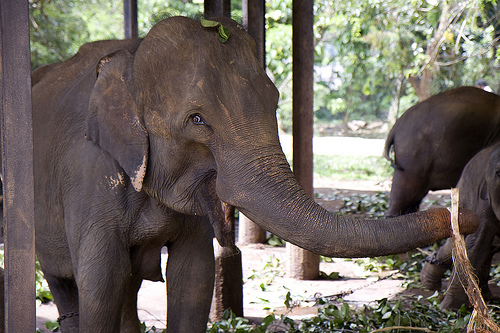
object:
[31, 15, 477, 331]
elephant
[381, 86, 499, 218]
elephant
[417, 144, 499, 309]
elephant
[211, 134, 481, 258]
trunk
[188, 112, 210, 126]
right eye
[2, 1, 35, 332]
beam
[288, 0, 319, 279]
beam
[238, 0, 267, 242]
beam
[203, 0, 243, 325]
beam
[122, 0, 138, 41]
beam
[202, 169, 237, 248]
mouth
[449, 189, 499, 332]
hay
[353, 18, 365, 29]
leaves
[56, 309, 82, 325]
chain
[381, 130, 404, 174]
tail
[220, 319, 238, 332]
leaves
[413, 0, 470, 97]
branch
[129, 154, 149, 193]
skin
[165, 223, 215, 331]
front left leg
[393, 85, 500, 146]
back end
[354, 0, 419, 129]
trees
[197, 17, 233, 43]
leaves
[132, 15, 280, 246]
head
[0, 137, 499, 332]
ground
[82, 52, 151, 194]
ear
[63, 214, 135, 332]
leg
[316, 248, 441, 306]
chain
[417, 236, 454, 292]
leg